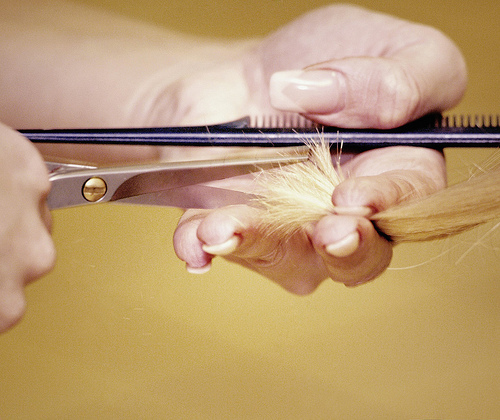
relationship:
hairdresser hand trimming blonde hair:
[136, 15, 439, 298] [362, 170, 499, 252]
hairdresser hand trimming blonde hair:
[2, 128, 72, 336] [362, 170, 499, 252]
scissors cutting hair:
[31, 144, 356, 253] [236, 138, 474, 241]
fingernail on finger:
[266, 67, 348, 115] [268, 3, 468, 128]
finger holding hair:
[264, 31, 466, 129] [232, 124, 499, 255]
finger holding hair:
[329, 144, 448, 217] [232, 124, 499, 255]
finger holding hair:
[311, 211, 396, 289] [232, 124, 499, 255]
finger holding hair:
[199, 200, 325, 295] [232, 124, 499, 255]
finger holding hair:
[171, 213, 215, 277] [232, 124, 499, 255]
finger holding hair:
[329, 165, 449, 216] [240, 123, 498, 269]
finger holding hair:
[311, 211, 396, 289] [240, 123, 498, 269]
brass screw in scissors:
[80, 177, 105, 202] [47, 152, 313, 210]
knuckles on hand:
[9, 114, 78, 332] [0, 118, 62, 347]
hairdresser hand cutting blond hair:
[156, 2, 470, 298] [202, 120, 500, 271]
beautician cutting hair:
[0, 0, 468, 337] [232, 124, 499, 255]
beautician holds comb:
[0, 0, 468, 337] [7, 90, 487, 172]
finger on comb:
[265, 0, 467, 131] [21, 111, 499, 151]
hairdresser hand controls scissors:
[0, 119, 58, 335] [31, 149, 316, 216]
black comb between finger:
[12, 111, 500, 148] [253, 47, 483, 139]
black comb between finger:
[12, 111, 500, 148] [306, 154, 466, 214]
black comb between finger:
[12, 111, 500, 148] [304, 208, 414, 289]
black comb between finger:
[12, 111, 500, 148] [199, 200, 325, 295]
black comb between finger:
[12, 111, 500, 148] [158, 208, 218, 274]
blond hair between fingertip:
[202, 120, 500, 271] [325, 173, 410, 210]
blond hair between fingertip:
[202, 120, 500, 271] [296, 214, 369, 269]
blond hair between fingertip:
[202, 120, 500, 271] [198, 208, 254, 258]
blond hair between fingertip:
[202, 120, 500, 271] [175, 222, 214, 279]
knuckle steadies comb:
[368, 57, 424, 129] [63, 117, 494, 146]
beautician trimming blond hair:
[0, 0, 468, 337] [246, 120, 497, 269]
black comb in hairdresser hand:
[17, 112, 498, 152] [156, 2, 470, 298]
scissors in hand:
[43, 155, 311, 212] [2, 120, 57, 335]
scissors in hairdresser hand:
[43, 155, 311, 212] [156, 2, 470, 298]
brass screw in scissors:
[80, 175, 110, 203] [48, 153, 325, 215]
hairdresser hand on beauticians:
[156, 2, 470, 298] [13, 5, 492, 413]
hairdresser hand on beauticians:
[0, 119, 58, 335] [13, 5, 492, 413]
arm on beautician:
[1, 3, 174, 173] [9, 5, 472, 344]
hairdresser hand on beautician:
[156, 2, 470, 298] [9, 5, 472, 344]